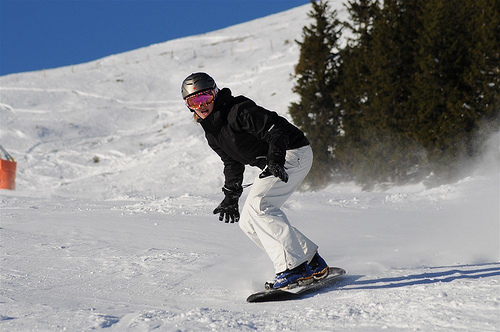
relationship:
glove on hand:
[212, 191, 240, 224] [216, 197, 236, 222]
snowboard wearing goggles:
[244, 266, 345, 303] [183, 81, 221, 108]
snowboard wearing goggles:
[244, 266, 345, 303] [186, 87, 218, 110]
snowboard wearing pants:
[244, 266, 345, 303] [236, 142, 319, 276]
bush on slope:
[290, 0, 497, 192] [2, 0, 497, 328]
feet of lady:
[271, 254, 330, 291] [180, 72, 328, 291]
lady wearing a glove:
[180, 72, 328, 291] [211, 186, 241, 221]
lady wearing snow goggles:
[180, 72, 328, 291] [186, 90, 213, 107]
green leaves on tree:
[413, 68, 428, 91] [292, 3, 498, 181]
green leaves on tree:
[321, 39, 466, 149] [292, 3, 498, 181]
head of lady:
[181, 72, 220, 118] [180, 72, 328, 291]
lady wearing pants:
[180, 72, 328, 291] [236, 142, 319, 276]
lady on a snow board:
[180, 72, 328, 291] [242, 263, 349, 303]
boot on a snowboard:
[262, 264, 315, 286] [245, 263, 347, 304]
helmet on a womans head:
[181, 70, 216, 99] [181, 72, 220, 118]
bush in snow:
[290, 0, 500, 192] [364, 187, 456, 258]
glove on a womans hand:
[212, 185, 240, 226] [210, 193, 242, 225]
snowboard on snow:
[244, 265, 350, 306] [2, 2, 499, 329]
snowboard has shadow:
[244, 266, 345, 303] [345, 257, 498, 295]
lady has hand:
[180, 72, 328, 291] [258, 165, 289, 183]